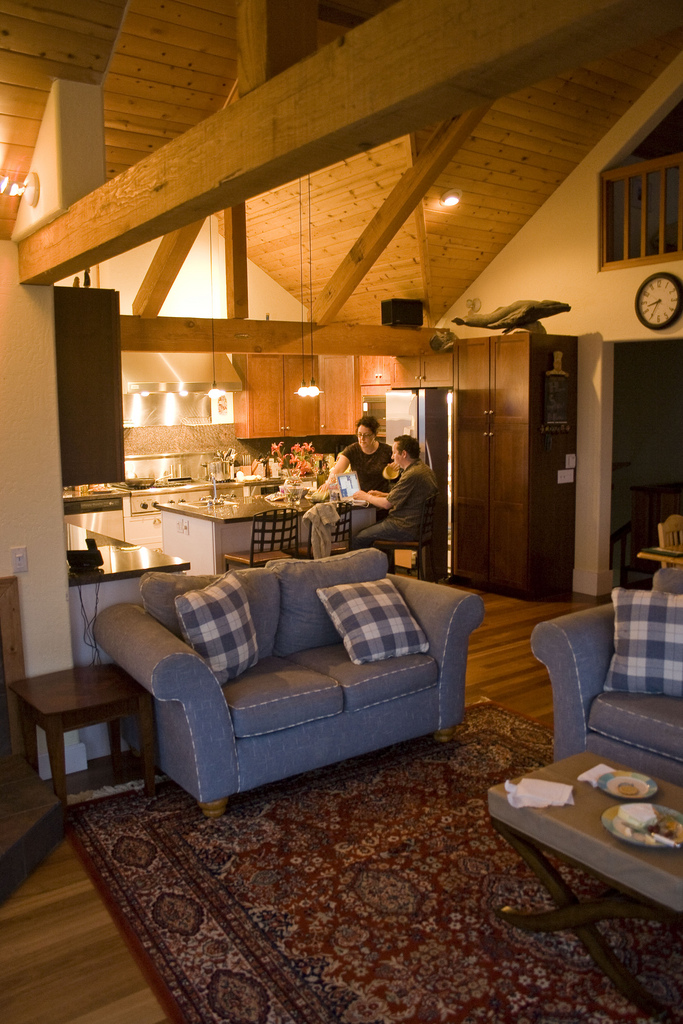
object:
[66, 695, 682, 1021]
area rug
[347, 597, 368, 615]
white square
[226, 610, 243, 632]
square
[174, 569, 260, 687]
pillow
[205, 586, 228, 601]
square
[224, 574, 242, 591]
square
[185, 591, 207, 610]
square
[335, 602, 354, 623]
square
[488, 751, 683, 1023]
coffee table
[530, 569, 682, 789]
couch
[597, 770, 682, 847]
plate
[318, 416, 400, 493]
woman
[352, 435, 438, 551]
man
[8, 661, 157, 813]
table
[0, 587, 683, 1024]
floor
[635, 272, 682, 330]
clock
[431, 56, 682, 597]
wall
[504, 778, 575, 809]
napkin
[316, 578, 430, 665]
pillow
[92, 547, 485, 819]
couch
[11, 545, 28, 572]
switch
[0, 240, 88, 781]
wall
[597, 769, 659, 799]
plate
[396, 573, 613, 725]
skillet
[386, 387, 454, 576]
stove